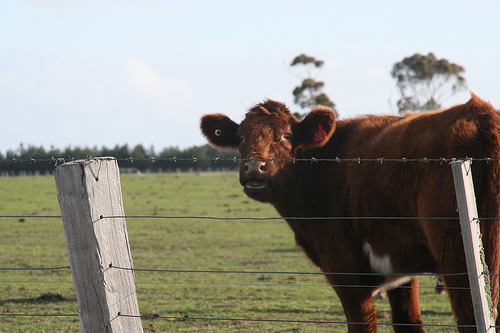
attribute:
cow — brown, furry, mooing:
[200, 91, 499, 331]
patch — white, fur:
[362, 240, 411, 296]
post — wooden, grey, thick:
[54, 156, 144, 332]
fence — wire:
[0, 154, 499, 332]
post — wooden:
[450, 158, 496, 332]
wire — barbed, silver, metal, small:
[1, 154, 500, 164]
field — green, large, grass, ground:
[0, 171, 459, 332]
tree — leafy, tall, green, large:
[290, 53, 339, 121]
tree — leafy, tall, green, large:
[390, 52, 466, 111]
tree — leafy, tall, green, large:
[130, 144, 148, 174]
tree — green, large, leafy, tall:
[116, 142, 132, 174]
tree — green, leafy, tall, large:
[157, 145, 181, 173]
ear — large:
[199, 113, 240, 151]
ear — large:
[297, 104, 337, 150]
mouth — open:
[244, 176, 268, 189]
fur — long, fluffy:
[200, 91, 498, 331]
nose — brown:
[243, 160, 268, 176]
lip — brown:
[244, 176, 266, 183]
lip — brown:
[244, 181, 267, 190]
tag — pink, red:
[313, 123, 328, 143]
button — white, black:
[214, 128, 222, 136]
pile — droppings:
[37, 291, 66, 301]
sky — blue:
[1, 1, 500, 159]